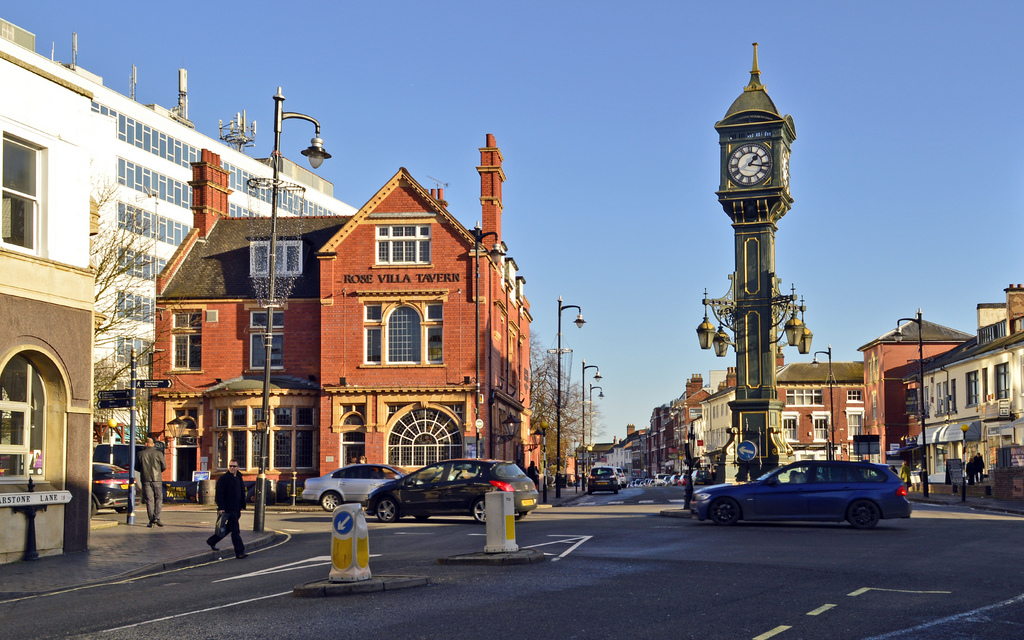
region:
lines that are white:
[778, 575, 870, 620]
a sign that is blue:
[322, 505, 358, 540]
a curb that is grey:
[303, 569, 436, 596]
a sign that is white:
[0, 481, 78, 511]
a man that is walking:
[214, 454, 268, 556]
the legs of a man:
[195, 515, 259, 558]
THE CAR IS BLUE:
[661, 437, 936, 542]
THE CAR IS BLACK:
[355, 446, 537, 522]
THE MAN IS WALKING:
[190, 444, 258, 559]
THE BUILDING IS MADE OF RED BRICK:
[121, 118, 551, 527]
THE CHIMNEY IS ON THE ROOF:
[463, 105, 517, 254]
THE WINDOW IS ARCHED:
[371, 394, 479, 483]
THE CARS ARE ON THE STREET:
[292, 456, 922, 529]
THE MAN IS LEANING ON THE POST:
[111, 430, 181, 525]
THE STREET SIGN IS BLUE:
[117, 339, 179, 536]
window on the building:
[0, 455, 36, 478]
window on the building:
[416, 293, 440, 358]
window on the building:
[390, 301, 425, 356]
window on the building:
[358, 309, 388, 368]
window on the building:
[157, 323, 196, 378]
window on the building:
[408, 424, 465, 470]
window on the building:
[234, 414, 304, 463]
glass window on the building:
[169, 330, 199, 368]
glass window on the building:
[253, 239, 263, 274]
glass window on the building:
[283, 239, 294, 271]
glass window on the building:
[377, 235, 388, 261]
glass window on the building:
[387, 232, 398, 256]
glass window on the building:
[400, 236, 413, 262]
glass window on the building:
[416, 232, 423, 256]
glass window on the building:
[364, 321, 380, 360]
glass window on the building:
[427, 325, 440, 361]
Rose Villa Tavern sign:
[329, 265, 478, 297]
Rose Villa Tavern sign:
[326, 247, 478, 308]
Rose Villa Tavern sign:
[321, 259, 476, 302]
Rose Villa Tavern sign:
[330, 260, 483, 299]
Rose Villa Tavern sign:
[333, 256, 471, 299]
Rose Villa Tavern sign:
[339, 266, 489, 302]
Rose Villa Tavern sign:
[343, 258, 476, 303]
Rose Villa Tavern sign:
[339, 265, 483, 297]